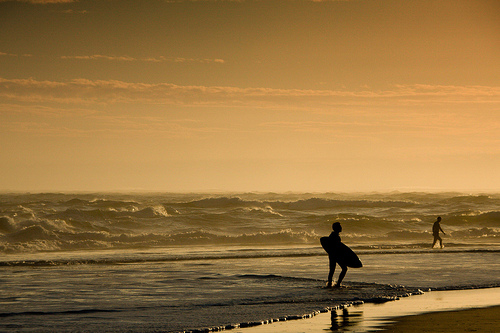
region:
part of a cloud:
[376, 85, 401, 97]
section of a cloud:
[252, 127, 259, 139]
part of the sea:
[231, 292, 241, 303]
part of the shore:
[267, 292, 291, 327]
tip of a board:
[350, 255, 352, 259]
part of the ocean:
[153, 177, 163, 227]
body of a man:
[433, 219, 437, 241]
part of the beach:
[430, 268, 437, 318]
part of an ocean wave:
[263, 269, 268, 275]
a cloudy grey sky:
[4, 3, 496, 192]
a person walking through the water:
[425, 211, 446, 254]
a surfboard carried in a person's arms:
[315, 216, 366, 287]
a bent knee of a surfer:
[336, 257, 348, 273]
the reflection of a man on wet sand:
[330, 300, 360, 325]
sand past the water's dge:
[375, 300, 490, 325]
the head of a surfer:
[330, 220, 340, 230]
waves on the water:
[0, 190, 490, 235]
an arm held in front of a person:
[436, 226, 447, 236]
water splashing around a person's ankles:
[329, 278, 343, 288]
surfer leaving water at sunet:
[320, 220, 366, 292]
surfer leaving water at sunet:
[428, 210, 452, 255]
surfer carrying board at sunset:
[310, 211, 359, 298]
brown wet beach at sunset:
[418, 297, 490, 327]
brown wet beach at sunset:
[264, 291, 397, 324]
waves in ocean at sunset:
[11, 250, 308, 320]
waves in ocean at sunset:
[13, 195, 313, 245]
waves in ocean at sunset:
[446, 192, 495, 266]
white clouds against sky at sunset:
[19, 12, 316, 184]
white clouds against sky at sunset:
[291, 3, 485, 181]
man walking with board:
[52, 25, 497, 285]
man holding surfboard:
[294, 207, 364, 300]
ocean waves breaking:
[40, 178, 247, 268]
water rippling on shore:
[153, 273, 315, 330]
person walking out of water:
[403, 204, 460, 265]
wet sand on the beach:
[335, 283, 469, 328]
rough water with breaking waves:
[106, 179, 375, 251]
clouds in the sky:
[31, 38, 392, 149]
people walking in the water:
[208, 153, 460, 283]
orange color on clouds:
[356, 63, 434, 150]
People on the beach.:
[303, 203, 455, 290]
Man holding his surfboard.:
[316, 212, 361, 288]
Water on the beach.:
[319, 298, 499, 332]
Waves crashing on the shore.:
[7, 193, 292, 255]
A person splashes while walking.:
[422, 240, 449, 253]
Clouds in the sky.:
[15, 56, 497, 147]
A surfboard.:
[317, 233, 364, 270]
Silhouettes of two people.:
[311, 201, 449, 286]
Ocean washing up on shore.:
[28, 268, 264, 330]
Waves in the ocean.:
[22, 189, 287, 253]